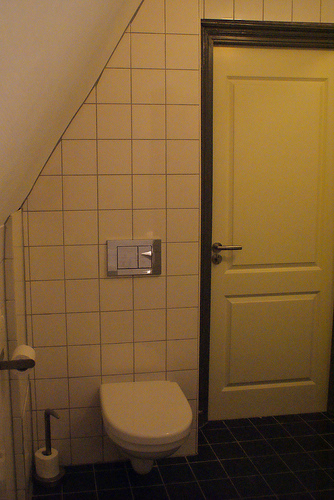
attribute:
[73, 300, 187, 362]
tile — bathroom, white, wall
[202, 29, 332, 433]
door — one, closed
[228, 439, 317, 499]
floor — tiled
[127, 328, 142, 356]
tiles — white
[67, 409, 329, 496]
tile — black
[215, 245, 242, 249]
handle — long and silver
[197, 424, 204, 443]
frame — dark and wooden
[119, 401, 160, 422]
toilet — white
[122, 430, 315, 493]
tile — brown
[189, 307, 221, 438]
trim — brown